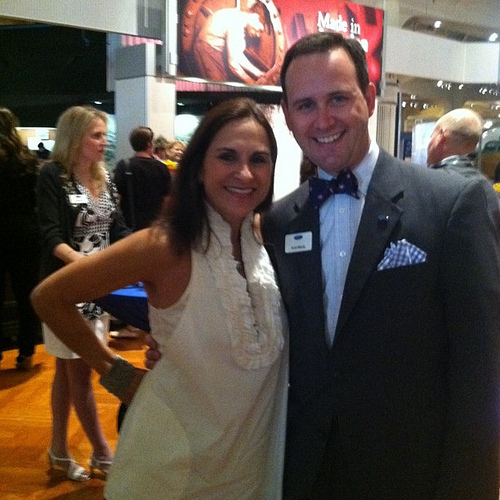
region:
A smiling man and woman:
[162, 15, 425, 261]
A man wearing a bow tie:
[278, 33, 398, 206]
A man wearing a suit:
[268, 47, 485, 488]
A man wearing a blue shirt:
[269, 42, 451, 330]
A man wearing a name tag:
[272, 41, 457, 316]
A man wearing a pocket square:
[269, 45, 460, 320]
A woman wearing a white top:
[125, 76, 295, 493]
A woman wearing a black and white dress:
[30, 95, 122, 477]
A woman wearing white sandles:
[35, 101, 114, 487]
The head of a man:
[276, 45, 381, 165]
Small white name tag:
[275, 229, 319, 256]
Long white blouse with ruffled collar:
[137, 203, 293, 496]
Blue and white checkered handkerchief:
[367, 235, 427, 272]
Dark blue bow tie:
[300, 165, 362, 205]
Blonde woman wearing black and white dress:
[16, 105, 126, 477]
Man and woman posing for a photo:
[135, 30, 436, 495]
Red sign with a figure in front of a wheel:
[145, 0, 400, 75]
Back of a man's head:
[423, 100, 485, 173]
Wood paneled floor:
[0, 335, 145, 490]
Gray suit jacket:
[271, 182, 498, 496]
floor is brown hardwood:
[21, 345, 164, 489]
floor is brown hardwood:
[46, 385, 121, 490]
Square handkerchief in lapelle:
[383, 238, 454, 348]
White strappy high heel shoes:
[35, 431, 93, 498]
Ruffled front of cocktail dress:
[205, 241, 295, 387]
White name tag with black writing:
[272, 227, 325, 284]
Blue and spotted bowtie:
[303, 170, 369, 218]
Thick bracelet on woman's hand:
[83, 341, 163, 419]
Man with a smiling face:
[273, 50, 396, 208]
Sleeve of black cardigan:
[36, 143, 83, 255]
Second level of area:
[386, 5, 497, 85]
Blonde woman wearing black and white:
[28, 101, 111, 348]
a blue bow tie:
[300, 163, 366, 213]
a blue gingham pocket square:
[373, 236, 440, 280]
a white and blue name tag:
[284, 223, 316, 254]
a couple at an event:
[27, 31, 494, 495]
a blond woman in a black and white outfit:
[27, 91, 136, 489]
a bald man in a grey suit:
[422, 98, 499, 186]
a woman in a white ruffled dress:
[33, 88, 289, 496]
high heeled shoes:
[37, 446, 124, 490]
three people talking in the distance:
[114, 122, 186, 210]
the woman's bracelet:
[90, 345, 140, 407]